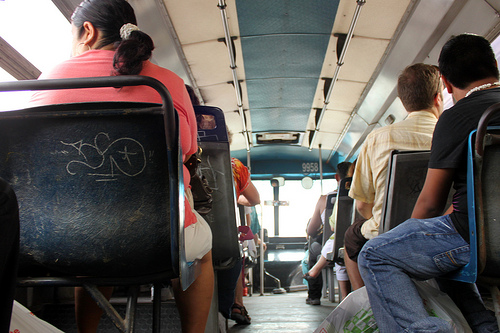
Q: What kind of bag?
A: Shopping bag.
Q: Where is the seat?
A: Bus.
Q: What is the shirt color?
A: Red.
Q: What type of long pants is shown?
A: Jeans.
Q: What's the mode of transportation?
A: Bus.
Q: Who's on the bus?
A: The people.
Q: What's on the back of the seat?
A: Graffiti.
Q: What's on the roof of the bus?
A: Poles.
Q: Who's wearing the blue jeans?
A: The sitting man.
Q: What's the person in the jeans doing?
A: Sitting.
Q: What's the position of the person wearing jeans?
A: Sitting.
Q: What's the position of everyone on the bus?
A: Sitting.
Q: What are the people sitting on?
A: Bus seats.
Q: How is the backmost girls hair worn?
A: Ponytail.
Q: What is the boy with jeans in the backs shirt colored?
A: Black.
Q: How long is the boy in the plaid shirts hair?
A: Short.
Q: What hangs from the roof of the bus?
A: Hand rails.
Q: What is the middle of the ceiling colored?
A: Blue.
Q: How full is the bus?
A: Full.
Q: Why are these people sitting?
A: They are riding a bus.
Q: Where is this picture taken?
A: A bus.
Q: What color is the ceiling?
A: Blue.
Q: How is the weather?
A: Sunny.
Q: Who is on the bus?
A: Men and women.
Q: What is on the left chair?
A: Graffiti.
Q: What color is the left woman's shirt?
A: Salmon.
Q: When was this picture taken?
A: Daytime.